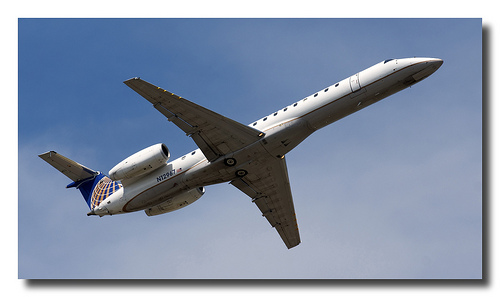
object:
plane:
[38, 56, 444, 251]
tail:
[37, 149, 124, 214]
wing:
[229, 155, 301, 249]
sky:
[16, 16, 481, 280]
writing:
[160, 175, 164, 181]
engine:
[108, 142, 170, 181]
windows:
[335, 83, 340, 87]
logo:
[90, 175, 123, 210]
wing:
[123, 76, 266, 163]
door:
[347, 72, 362, 93]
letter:
[157, 176, 162, 182]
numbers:
[171, 169, 175, 174]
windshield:
[384, 59, 394, 64]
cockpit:
[384, 58, 398, 65]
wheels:
[235, 169, 249, 178]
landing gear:
[223, 157, 248, 177]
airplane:
[38, 56, 443, 248]